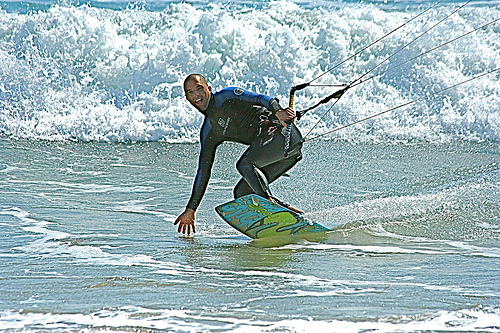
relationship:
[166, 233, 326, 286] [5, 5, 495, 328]
shadow in water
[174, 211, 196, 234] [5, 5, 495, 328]
hand in water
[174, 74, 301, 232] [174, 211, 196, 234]
man has hand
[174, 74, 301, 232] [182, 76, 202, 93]
man has forehead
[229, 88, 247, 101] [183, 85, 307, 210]
logo on wet suit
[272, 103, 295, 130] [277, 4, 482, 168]
hand holding cords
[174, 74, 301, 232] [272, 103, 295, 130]
man has hand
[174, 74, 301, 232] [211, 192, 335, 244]
man on surfboard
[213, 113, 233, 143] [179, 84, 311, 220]
logo on body suit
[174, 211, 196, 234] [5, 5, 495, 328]
hand touching water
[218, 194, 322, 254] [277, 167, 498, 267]
surfboard riding waves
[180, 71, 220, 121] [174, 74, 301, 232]
head of man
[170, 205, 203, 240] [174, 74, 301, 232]
hand of man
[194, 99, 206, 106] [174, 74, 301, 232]
mouth of man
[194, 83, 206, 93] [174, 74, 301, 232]
eye of man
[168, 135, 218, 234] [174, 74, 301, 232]
arm of man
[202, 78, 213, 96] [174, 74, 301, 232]
ear of man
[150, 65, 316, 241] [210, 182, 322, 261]
man on surfboard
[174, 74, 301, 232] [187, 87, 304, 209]
man in body suit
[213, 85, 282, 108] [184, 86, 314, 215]
fabric from suit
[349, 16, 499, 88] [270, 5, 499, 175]
cords from contraption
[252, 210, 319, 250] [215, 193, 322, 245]
s on bottom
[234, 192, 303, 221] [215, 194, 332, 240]
feet on surfboard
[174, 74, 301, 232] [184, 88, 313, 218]
man wearing wetsuit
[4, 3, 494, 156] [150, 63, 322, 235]
wave behind surfer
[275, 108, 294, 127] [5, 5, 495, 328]
hand touching water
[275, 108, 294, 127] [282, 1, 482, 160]
hand holding parasail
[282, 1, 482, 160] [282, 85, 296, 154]
parasail attached to handle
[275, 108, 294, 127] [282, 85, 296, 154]
hand holding handle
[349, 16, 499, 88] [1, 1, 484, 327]
cords hanging in air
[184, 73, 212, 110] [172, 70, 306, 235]
head belonging to man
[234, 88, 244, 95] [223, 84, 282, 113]
logo adorning right arm